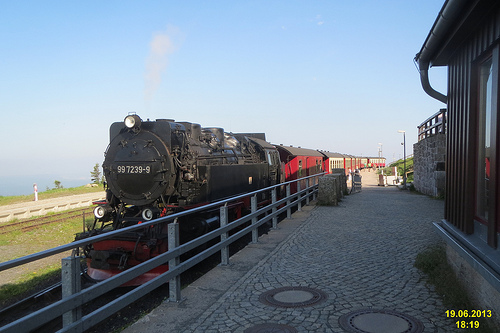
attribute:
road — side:
[2, 182, 104, 226]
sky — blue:
[18, 20, 435, 137]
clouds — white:
[14, 108, 116, 158]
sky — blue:
[0, 0, 447, 194]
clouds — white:
[274, 5, 329, 34]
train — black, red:
[70, 99, 395, 291]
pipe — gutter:
[414, 49, 451, 113]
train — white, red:
[97, 100, 402, 246]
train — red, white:
[93, 62, 394, 271]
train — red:
[37, 64, 359, 237]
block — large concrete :
[315, 172, 342, 205]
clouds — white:
[273, 80, 383, 149]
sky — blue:
[270, 19, 378, 74]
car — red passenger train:
[272, 136, 349, 217]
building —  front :
[408, 0, 498, 325]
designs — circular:
[258, 276, 327, 311]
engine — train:
[80, 200, 189, 280]